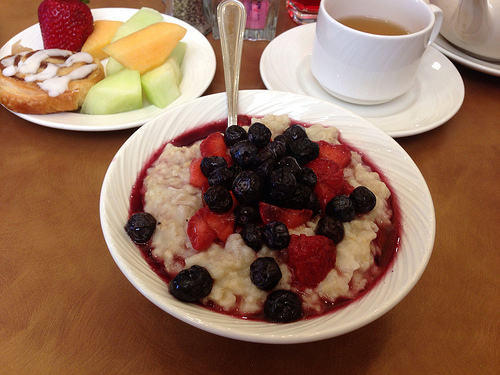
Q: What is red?
A: Strawberries.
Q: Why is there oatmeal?
A: Breakfast.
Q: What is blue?
A: Blueberries.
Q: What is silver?
A: Spoon.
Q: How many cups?
A: One.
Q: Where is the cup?
A: On the saucer.